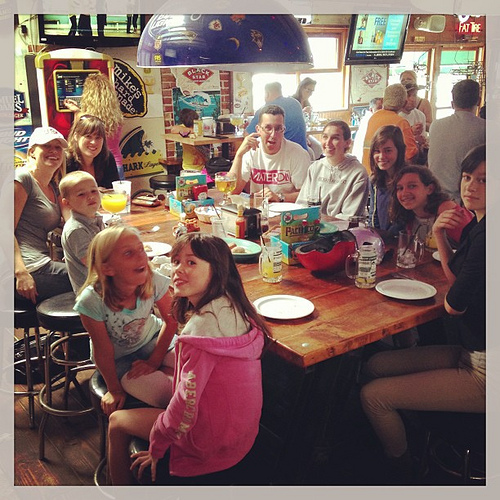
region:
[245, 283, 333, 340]
plate on the table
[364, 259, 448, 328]
plate on the table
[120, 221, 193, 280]
plate on the table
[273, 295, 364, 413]
table is made of wood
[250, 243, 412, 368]
table is made of wood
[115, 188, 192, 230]
table is made of wood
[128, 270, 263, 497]
the jacket is pink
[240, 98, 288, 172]
man is wearing eyeglasses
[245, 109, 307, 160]
man is wearing eyeglasses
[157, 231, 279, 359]
Little girl with brown hair looking at camera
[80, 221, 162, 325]
Girl with blonde hair looking to the right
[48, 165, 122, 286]
Litte boy sitting on the barstool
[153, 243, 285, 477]
Girl in pink and white jacket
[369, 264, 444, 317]
Small white empty paper plate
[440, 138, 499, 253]
Woman with dark hair looking at the camera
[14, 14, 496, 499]
Large group of people eating and smiling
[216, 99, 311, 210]
Man with red and white shirt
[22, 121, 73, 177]
Woman with white baseball cap on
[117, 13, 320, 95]
Large blue lamp hanging over table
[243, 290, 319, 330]
Round white plate waiting for food.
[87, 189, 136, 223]
Looks like someone is enjoying a drink.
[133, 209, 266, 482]
Girl in a pink sweat jacket.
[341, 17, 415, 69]
Flat screen tv hanging from the wall.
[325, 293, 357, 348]
Large brown wooden table.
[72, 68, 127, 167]
Girl with blonde hair playing the juke box.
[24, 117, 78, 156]
Woman wearing a white cap.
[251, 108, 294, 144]
Man wearing dark framed glasses.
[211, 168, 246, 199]
Glass of beer on the table.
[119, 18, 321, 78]
Blue light over the table.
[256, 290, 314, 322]
white plate on the table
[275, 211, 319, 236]
the restaurant menu on table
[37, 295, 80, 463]
black stool at the table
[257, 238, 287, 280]
a glass with yellow beverage in it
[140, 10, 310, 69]
a half-domed blue ceiling light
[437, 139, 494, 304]
girl in black touching chin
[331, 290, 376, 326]
a part of the wooden table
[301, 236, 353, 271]
a red helmet on the table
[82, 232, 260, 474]
two girls sitting at the table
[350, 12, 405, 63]
a flat screen mounted on wall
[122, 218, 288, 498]
girl wearing pink jacket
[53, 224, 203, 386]
girl wearing blue shirt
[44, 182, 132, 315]
boy wearing grey shirt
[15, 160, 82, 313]
lady wearing grey shirt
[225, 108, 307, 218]
man wearing white shirt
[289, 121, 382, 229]
lady wearing grey hoodie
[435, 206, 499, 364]
lady wearing black shirt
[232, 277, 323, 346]
white plate on table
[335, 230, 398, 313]
mug on the table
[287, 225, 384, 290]
red hard helmet on the table